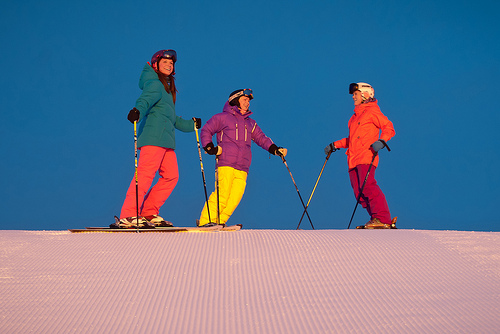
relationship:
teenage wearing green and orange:
[109, 50, 202, 230] [117, 61, 195, 219]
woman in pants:
[197, 89, 289, 229] [199, 166, 247, 226]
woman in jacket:
[197, 89, 289, 229] [200, 101, 279, 175]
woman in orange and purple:
[324, 81, 397, 231] [330, 101, 398, 226]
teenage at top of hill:
[109, 50, 202, 230] [1, 229, 500, 334]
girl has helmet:
[324, 80, 399, 231] [347, 82, 375, 103]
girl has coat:
[324, 80, 399, 231] [332, 100, 396, 172]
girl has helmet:
[196, 89, 288, 229] [227, 87, 254, 108]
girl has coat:
[196, 89, 288, 229] [200, 101, 282, 176]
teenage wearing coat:
[109, 50, 202, 230] [133, 61, 196, 152]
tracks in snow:
[1, 228, 500, 333] [1, 228, 499, 332]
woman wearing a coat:
[324, 81, 397, 231] [332, 100, 396, 172]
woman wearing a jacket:
[197, 89, 289, 229] [200, 101, 279, 175]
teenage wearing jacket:
[118, 50, 202, 230] [131, 61, 196, 151]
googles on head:
[161, 48, 178, 62] [152, 49, 178, 76]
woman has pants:
[324, 81, 397, 231] [347, 163, 394, 226]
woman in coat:
[324, 81, 397, 231] [332, 100, 396, 173]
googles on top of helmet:
[347, 82, 359, 94] [347, 82, 375, 103]